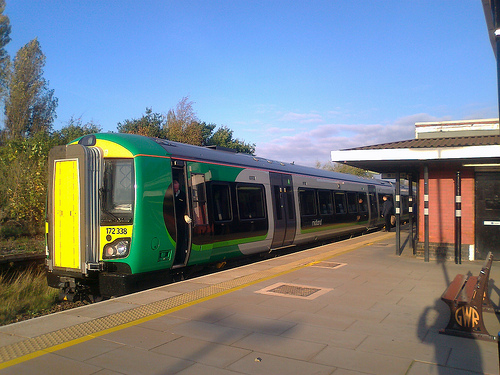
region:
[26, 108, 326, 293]
a green, yellow and white passenger train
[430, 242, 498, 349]
a bench at the the platform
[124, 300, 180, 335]
a solid yellow line in the platform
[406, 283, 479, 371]
a shadow of a person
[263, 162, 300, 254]
an automatic door of a train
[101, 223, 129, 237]
a number of a train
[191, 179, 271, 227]
windows of a train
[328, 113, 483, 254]
a waiting area at the stain station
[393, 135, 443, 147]
roof of the waiting area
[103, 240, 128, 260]
lights at the back of the train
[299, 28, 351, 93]
part of the sky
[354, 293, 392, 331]
part of a floor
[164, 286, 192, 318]
part of a line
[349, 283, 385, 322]
part of a floor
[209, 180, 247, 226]
part of a window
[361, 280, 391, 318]
part of a floor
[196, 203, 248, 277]
part of a train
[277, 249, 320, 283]
part of a floor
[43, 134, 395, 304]
a green and yellow train car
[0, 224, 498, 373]
a train boarding platform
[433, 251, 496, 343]
a wooden park bench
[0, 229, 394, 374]
a long yellow stripe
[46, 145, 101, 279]
a flexible train connector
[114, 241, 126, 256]
a train headlight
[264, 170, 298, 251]
a train exit entry door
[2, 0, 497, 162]
a deep blue sky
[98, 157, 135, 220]
a train windshield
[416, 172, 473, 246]
a red brick wall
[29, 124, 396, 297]
a train on railroad track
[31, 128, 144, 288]
front of train is yellow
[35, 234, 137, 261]
headlights of train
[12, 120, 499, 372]
an open train station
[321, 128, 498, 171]
roof of train station is black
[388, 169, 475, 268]
poles supporting a roof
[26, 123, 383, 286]
train is color yellow, green and white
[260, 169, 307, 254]
door of train is color gray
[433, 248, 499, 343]
a brown bench on a train station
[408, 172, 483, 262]
a red wall with black base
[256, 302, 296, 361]
part of a floor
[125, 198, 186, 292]
part of a train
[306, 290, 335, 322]
part of a floor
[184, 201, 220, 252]
part of a train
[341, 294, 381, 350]
part of a floor